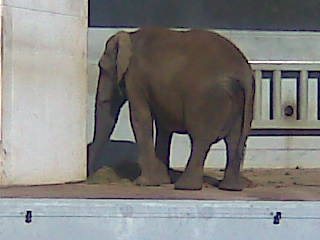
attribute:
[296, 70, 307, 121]
bar — vertical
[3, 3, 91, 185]
wall — white, stone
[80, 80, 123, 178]
trunk — long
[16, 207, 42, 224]
piece — black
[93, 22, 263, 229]
elephant — standing alone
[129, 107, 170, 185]
leg — front leg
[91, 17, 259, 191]
elephant — brown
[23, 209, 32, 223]
mark — black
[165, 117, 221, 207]
elephant leg — rear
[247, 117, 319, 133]
bar — horitzontal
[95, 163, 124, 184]
grass — green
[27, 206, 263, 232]
wall — grey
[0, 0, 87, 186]
surface — white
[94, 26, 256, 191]
large elephant — brown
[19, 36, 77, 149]
wall — white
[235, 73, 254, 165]
tail — long